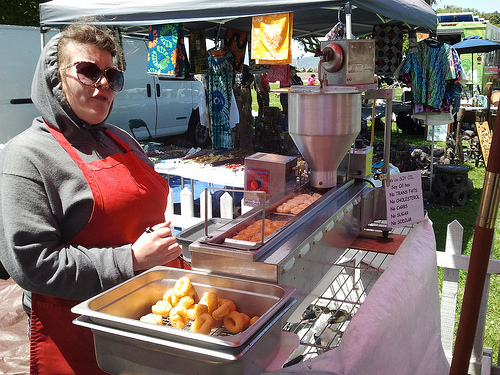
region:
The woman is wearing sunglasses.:
[66, 57, 137, 99]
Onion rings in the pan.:
[131, 288, 245, 338]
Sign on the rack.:
[390, 172, 431, 225]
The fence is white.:
[429, 233, 472, 295]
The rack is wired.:
[304, 284, 369, 341]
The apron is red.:
[94, 167, 156, 212]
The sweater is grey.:
[14, 180, 57, 222]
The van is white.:
[139, 91, 199, 121]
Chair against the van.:
[126, 121, 170, 156]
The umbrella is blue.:
[434, 34, 499, 68]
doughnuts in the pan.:
[171, 293, 206, 320]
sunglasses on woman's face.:
[76, 62, 101, 89]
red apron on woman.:
[103, 177, 152, 204]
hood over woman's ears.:
[43, 31, 63, 94]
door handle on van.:
[145, 85, 155, 97]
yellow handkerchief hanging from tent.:
[253, 20, 289, 60]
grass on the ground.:
[487, 292, 494, 332]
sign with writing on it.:
[387, 173, 420, 230]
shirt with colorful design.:
[420, 51, 440, 95]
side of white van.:
[8, 39, 23, 76]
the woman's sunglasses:
[57, 59, 128, 92]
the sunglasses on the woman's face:
[58, 61, 128, 91]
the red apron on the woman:
[27, 115, 194, 372]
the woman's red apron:
[27, 114, 187, 371]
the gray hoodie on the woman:
[0, 28, 138, 280]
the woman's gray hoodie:
[0, 30, 147, 284]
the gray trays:
[67, 262, 299, 368]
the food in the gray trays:
[142, 275, 244, 335]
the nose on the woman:
[90, 72, 108, 89]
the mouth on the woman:
[89, 90, 114, 103]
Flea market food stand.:
[11, 23, 335, 368]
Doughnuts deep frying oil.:
[224, 200, 343, 267]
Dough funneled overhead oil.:
[279, 66, 370, 210]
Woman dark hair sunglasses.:
[28, 15, 155, 143]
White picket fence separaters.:
[156, 170, 253, 236]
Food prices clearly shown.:
[356, 150, 434, 247]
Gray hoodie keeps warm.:
[20, 32, 108, 259]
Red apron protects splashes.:
[25, 106, 161, 296]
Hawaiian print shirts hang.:
[379, 9, 477, 141]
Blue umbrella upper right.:
[429, 20, 499, 120]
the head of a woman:
[29, 15, 128, 125]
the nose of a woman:
[90, 68, 111, 91]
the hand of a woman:
[127, 215, 186, 270]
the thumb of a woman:
[139, 216, 172, 240]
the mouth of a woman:
[83, 88, 114, 103]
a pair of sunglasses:
[50, 55, 127, 95]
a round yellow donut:
[184, 305, 215, 335]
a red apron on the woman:
[26, 110, 194, 371]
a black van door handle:
[141, 77, 153, 99]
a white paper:
[381, 169, 428, 231]